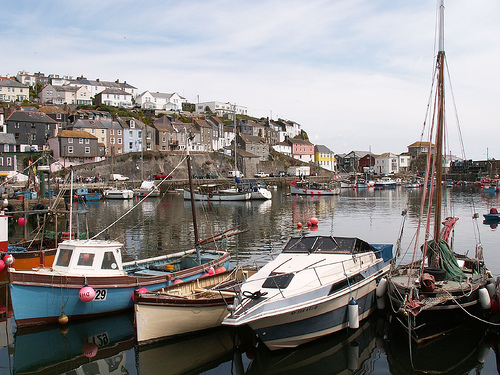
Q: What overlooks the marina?
A: A village on the hill.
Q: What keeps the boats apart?
A: Bumpers.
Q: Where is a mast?
A: On several boats with sails.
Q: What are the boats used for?
A: Pleasure and fishing.